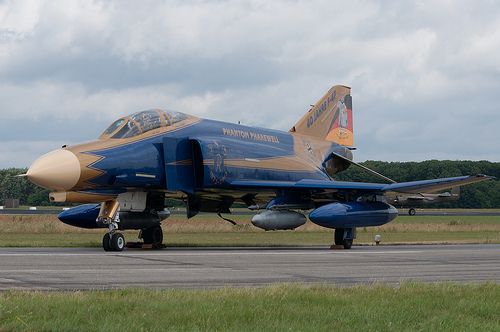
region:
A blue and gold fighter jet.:
[15, 22, 457, 279]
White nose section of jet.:
[17, 141, 82, 196]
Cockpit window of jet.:
[103, 99, 194, 138]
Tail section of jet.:
[288, 76, 363, 152]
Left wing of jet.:
[244, 157, 490, 202]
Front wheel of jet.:
[96, 217, 126, 252]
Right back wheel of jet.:
[320, 215, 360, 255]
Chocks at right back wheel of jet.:
[318, 222, 353, 253]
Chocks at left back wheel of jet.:
[139, 218, 169, 255]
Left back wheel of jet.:
[133, 217, 168, 254]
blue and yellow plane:
[17, 81, 425, 256]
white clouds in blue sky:
[17, 26, 78, 74]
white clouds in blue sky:
[400, 68, 435, 108]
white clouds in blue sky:
[397, 96, 482, 151]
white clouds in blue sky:
[387, 35, 468, 119]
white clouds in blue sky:
[300, 26, 357, 70]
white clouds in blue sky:
[217, 18, 281, 68]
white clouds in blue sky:
[227, 46, 277, 91]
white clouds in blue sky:
[175, 23, 239, 73]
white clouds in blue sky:
[137, 23, 208, 77]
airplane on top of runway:
[13, 83, 494, 254]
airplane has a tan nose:
[16, 146, 81, 193]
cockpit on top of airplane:
[100, 107, 189, 140]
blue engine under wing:
[308, 190, 398, 227]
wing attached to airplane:
[233, 169, 490, 201]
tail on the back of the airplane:
[289, 85, 359, 148]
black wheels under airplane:
[101, 231, 126, 252]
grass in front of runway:
[0, 279, 499, 329]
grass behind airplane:
[0, 211, 499, 247]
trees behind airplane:
[338, 159, 499, 206]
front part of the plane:
[22, 123, 89, 215]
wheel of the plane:
[91, 231, 148, 258]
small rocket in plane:
[240, 185, 309, 255]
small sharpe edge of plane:
[11, 161, 27, 193]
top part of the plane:
[93, 93, 180, 150]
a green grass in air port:
[22, 273, 494, 330]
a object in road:
[366, 225, 393, 260]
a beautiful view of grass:
[23, 277, 497, 324]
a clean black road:
[27, 240, 497, 295]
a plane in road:
[46, 80, 481, 250]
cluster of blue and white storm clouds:
[56, 34, 233, 111]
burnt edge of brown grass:
[156, 279, 331, 297]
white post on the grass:
[374, 233, 390, 245]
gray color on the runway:
[95, 248, 332, 275]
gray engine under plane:
[250, 200, 307, 234]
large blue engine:
[307, 196, 404, 228]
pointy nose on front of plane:
[7, 168, 38, 182]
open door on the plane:
[158, 130, 227, 186]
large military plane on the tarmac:
[27, 81, 470, 271]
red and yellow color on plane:
[324, 94, 362, 146]